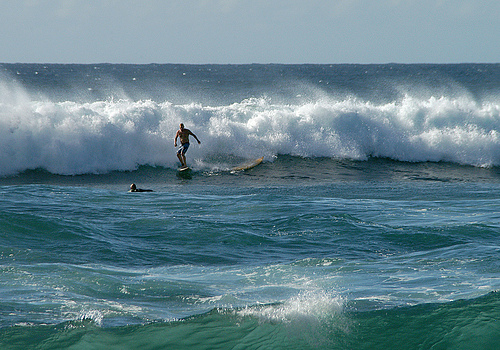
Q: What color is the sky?
A: Blue.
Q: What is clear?
A: Sky.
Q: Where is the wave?
A: Behind the surfer.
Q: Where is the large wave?
A: In the ocean.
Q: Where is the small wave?
A: In the ocean.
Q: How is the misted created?
A: By the water splashing.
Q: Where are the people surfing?
A: In the Ocean.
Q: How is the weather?
A: Clear.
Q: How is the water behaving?
A: Wave is breaking.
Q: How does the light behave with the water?
A: Shimmers.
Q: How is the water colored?
A: Blue.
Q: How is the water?
A: Rough.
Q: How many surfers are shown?
A: Two.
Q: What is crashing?
A: Waves.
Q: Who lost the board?
A: Surfer.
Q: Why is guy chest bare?
A: No shirt.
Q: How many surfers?
A: Two.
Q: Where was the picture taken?
A: Beach.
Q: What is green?
A: Water.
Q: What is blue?
A: Sky.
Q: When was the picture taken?
A: Daytime.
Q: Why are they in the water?
A: Surfing.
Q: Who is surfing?
A: Men.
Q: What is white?
A: Waves.